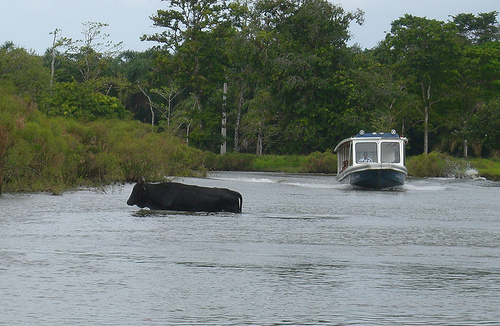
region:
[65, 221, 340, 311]
blue water in the creek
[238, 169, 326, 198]
path of white waves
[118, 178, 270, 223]
black cow in the water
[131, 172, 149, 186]
horns on cow's head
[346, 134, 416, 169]
white frame on mirrors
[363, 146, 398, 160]
clear mirror in front of boat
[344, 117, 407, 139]
blue top on boat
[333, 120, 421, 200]
blue boat in the water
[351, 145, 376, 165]
man in front of boat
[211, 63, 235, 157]
tall trunk on tree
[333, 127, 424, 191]
white boat in river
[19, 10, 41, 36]
white clouds in blue sky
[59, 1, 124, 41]
white clouds in blue sky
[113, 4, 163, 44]
white clouds in blue sky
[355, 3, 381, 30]
white clouds in blue sky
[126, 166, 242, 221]
overturned boat in river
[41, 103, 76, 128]
green leaves in brown trees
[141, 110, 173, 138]
green leaves in brown trees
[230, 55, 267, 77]
green leaves in brown trees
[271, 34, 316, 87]
green leaves in brown trees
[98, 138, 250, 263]
this is a cow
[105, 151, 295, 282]
the cow is in the water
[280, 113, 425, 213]
this is a ship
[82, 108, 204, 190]
this is a bushy tree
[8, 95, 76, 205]
this is a bushy tree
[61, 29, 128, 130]
this is a bushy tree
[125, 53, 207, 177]
this is a bushy tree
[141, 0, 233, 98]
this is a bushy tree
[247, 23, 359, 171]
this is a bushy tree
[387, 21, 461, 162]
this is a bushy tree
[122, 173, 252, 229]
Cow walking through the water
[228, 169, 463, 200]
wake made by the boat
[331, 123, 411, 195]
blue and white tourist boat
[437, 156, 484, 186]
water splashing ashore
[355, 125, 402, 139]
four clear lights on top of the boat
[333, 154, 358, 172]
people looking out the side of the boat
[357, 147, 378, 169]
person driving the boat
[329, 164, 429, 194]
blue bottom part of the boat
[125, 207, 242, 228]
reflection of the cow in the water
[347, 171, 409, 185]
wording on both sides of the boat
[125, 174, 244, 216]
Large black yak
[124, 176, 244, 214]
Large yak treading through water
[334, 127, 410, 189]
Boat driving in the water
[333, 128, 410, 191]
Silver and blue boat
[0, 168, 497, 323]
Low current river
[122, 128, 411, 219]
Boat and a yak in the water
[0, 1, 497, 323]
River and forest scenery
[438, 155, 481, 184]
Waves crashing onto shore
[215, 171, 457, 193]
Wake of a boat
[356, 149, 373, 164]
Man driving a boat